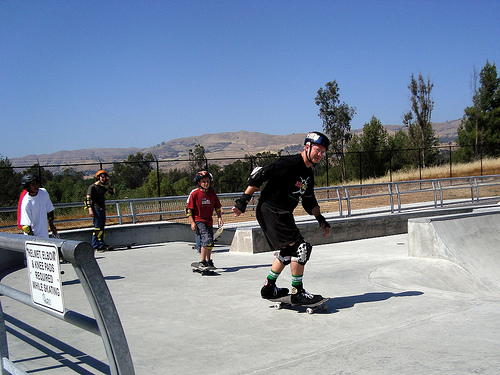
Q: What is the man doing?
A: Riding a skateboard.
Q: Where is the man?
A: In a skate park.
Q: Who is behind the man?
A: Boy in red shirt.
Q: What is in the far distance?
A: Low rocky hills.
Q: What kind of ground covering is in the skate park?
A: Gray pavement.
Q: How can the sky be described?
A: A blue cloudless sky.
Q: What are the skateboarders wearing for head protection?
A: Helmets.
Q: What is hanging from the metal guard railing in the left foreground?
A: A sign.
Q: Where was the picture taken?
A: In a skate park.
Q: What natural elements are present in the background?
A: Mountains and trees.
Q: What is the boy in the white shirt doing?
A: He is watching the others skate.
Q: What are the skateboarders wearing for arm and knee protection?
A: They are wearing elbow and knee pads.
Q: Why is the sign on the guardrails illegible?
A: It is out of focus.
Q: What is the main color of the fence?
A: Gray.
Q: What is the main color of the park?
A: Gray.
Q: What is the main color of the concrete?
A: Gray.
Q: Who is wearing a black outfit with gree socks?
A: The nearest skateboarder, an older one, who is wearing glasses.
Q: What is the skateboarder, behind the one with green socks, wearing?
A: A red shirt and knee length pants.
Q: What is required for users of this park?
A: The wearing of protective gear.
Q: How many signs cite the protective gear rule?
A: Just one.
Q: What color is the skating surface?
A: Grey.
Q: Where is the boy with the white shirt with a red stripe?
A: To the left, close to the fence.